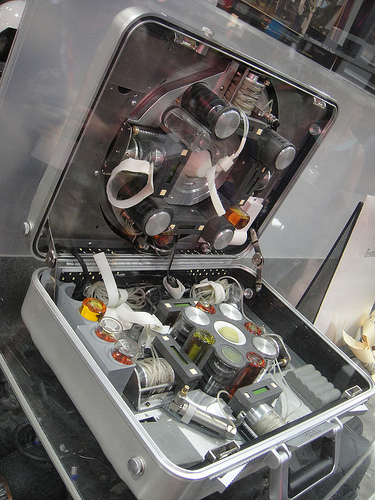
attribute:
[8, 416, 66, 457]
wires — black, tangled up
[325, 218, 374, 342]
white board — shiny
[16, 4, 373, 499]
suitcase — silver, metal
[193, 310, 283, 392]
pieces — silver